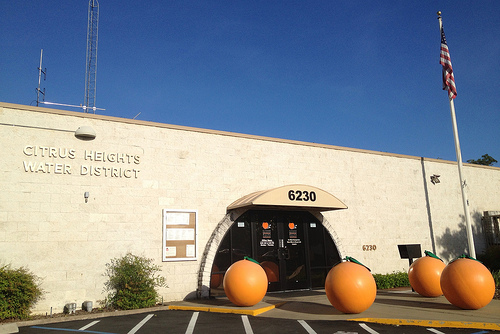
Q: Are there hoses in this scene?
A: No, there are no hoses.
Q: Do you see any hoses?
A: No, there are no hoses.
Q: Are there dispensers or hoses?
A: No, there are no hoses or dispensers.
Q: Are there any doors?
A: Yes, there is a door.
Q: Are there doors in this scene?
A: Yes, there is a door.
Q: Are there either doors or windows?
A: Yes, there is a door.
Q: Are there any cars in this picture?
A: No, there are no cars.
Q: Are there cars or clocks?
A: No, there are no cars or clocks.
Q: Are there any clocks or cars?
A: No, there are no cars or clocks.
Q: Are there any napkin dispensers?
A: No, there are no napkin dispensers.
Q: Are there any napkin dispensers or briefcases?
A: No, there are no napkin dispensers or briefcases.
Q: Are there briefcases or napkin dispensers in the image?
A: No, there are no napkin dispensers or briefcases.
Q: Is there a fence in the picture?
A: No, there are no fences.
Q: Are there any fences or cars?
A: No, there are no fences or cars.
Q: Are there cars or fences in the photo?
A: No, there are no fences or cars.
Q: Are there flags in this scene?
A: Yes, there is a flag.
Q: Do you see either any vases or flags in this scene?
A: Yes, there is a flag.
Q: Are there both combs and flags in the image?
A: No, there is a flag but no combs.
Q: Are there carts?
A: No, there are no carts.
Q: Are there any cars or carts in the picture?
A: No, there are no carts or cars.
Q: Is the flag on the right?
A: Yes, the flag is on the right of the image.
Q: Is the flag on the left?
A: No, the flag is on the right of the image.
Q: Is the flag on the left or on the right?
A: The flag is on the right of the image.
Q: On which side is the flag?
A: The flag is on the right of the image.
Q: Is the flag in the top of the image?
A: Yes, the flag is in the top of the image.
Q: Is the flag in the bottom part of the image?
A: No, the flag is in the top of the image.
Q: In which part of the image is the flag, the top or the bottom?
A: The flag is in the top of the image.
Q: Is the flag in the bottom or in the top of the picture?
A: The flag is in the top of the image.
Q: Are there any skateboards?
A: No, there are no skateboards.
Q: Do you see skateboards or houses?
A: No, there are no skateboards or houses.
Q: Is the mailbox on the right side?
A: Yes, the mailbox is on the right of the image.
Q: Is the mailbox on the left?
A: No, the mailbox is on the right of the image.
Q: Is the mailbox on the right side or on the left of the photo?
A: The mailbox is on the right of the image.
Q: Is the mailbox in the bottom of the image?
A: Yes, the mailbox is in the bottom of the image.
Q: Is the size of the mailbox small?
A: Yes, the mailbox is small.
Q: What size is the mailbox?
A: The mailbox is small.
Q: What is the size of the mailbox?
A: The mailbox is small.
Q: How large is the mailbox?
A: The mailbox is small.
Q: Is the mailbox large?
A: No, the mailbox is small.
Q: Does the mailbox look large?
A: No, the mailbox is small.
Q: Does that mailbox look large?
A: No, the mailbox is small.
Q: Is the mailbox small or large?
A: The mailbox is small.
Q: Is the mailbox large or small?
A: The mailbox is small.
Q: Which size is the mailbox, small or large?
A: The mailbox is small.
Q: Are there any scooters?
A: No, there are no scooters.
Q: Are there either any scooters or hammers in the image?
A: No, there are no scooters or hammers.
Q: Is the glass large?
A: Yes, the glass is large.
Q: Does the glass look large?
A: Yes, the glass is large.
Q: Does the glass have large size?
A: Yes, the glass is large.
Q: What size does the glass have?
A: The glass has large size.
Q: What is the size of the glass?
A: The glass is large.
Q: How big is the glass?
A: The glass is large.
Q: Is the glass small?
A: No, the glass is large.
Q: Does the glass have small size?
A: No, the glass is large.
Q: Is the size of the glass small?
A: No, the glass is large.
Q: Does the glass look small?
A: No, the glass is large.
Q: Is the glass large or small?
A: The glass is large.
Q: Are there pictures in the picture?
A: No, there are no pictures.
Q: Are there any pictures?
A: No, there are no pictures.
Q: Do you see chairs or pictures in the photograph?
A: No, there are no pictures or chairs.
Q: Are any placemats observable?
A: No, there are no placemats.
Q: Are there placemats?
A: No, there are no placemats.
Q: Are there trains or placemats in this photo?
A: No, there are no placemats or trains.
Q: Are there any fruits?
A: Yes, there is a fruit.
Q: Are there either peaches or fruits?
A: Yes, there is a fruit.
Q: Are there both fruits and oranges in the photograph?
A: Yes, there are both a fruit and oranges.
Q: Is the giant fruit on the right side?
A: Yes, the fruit is on the right of the image.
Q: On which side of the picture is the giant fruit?
A: The fruit is on the right of the image.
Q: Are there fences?
A: No, there are no fences.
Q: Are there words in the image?
A: Yes, there are words.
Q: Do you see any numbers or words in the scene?
A: Yes, there are words.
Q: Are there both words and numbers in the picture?
A: Yes, there are both words and numbers.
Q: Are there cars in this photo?
A: No, there are no cars.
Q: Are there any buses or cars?
A: No, there are no cars or buses.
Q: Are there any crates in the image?
A: No, there are no crates.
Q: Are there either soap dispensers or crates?
A: No, there are no crates or soap dispensers.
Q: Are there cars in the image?
A: No, there are no cars.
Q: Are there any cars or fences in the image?
A: No, there are no cars or fences.